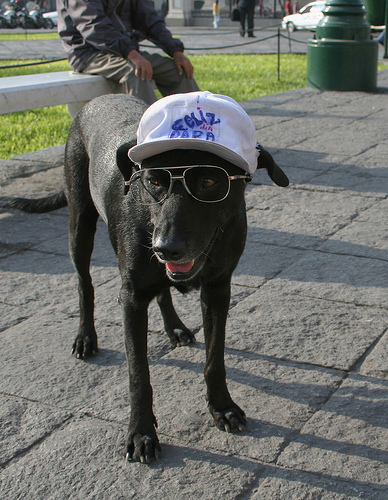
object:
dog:
[64, 90, 289, 462]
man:
[56, 0, 199, 105]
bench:
[0, 70, 119, 119]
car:
[280, 0, 329, 31]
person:
[228, 3, 256, 38]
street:
[6, 15, 388, 54]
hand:
[128, 49, 153, 81]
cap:
[127, 90, 260, 173]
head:
[115, 90, 289, 282]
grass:
[0, 32, 387, 158]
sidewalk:
[0, 66, 387, 500]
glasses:
[125, 164, 253, 206]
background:
[2, 1, 379, 141]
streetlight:
[304, 0, 379, 93]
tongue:
[164, 258, 196, 276]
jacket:
[57, 0, 185, 73]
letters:
[167, 106, 221, 142]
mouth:
[155, 234, 215, 283]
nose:
[152, 238, 166, 259]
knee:
[117, 53, 157, 90]